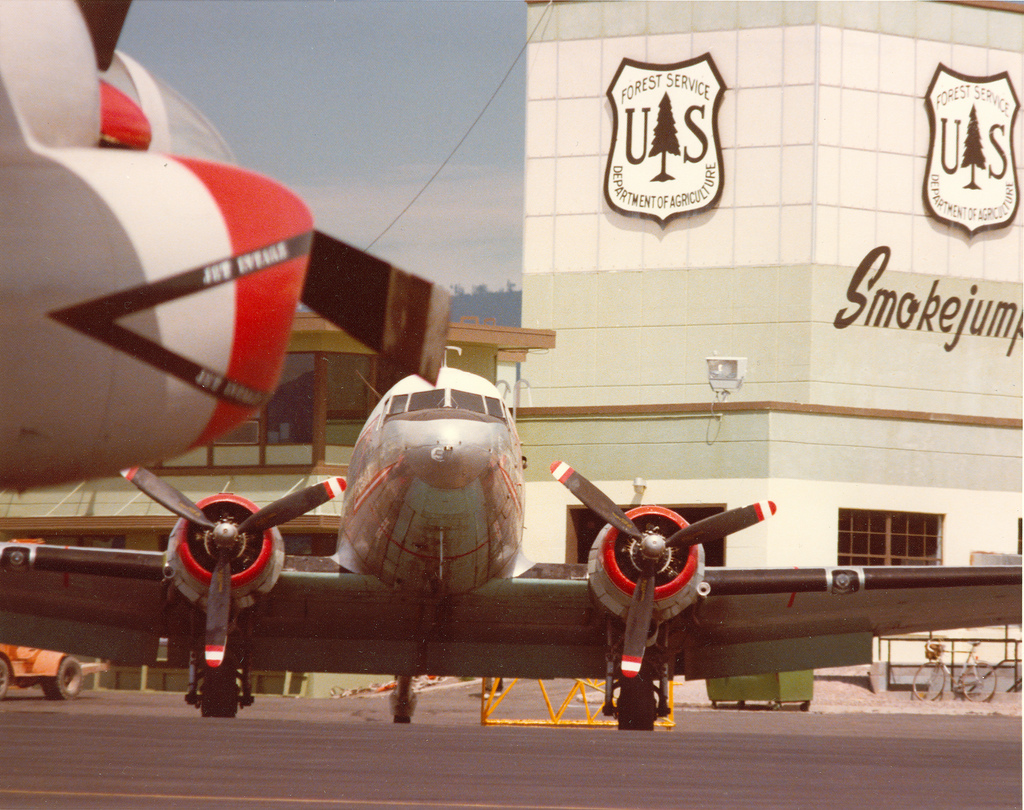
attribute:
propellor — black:
[544, 450, 784, 686]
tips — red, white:
[550, 457, 574, 494]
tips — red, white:
[751, 491, 775, 522]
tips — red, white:
[611, 659, 646, 686]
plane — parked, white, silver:
[0, 322, 1024, 739]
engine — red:
[557, 469, 776, 724]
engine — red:
[114, 444, 337, 673]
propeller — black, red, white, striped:
[89, 441, 368, 681]